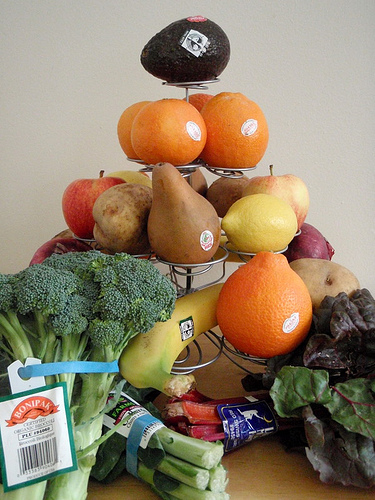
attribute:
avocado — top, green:
[140, 15, 232, 82]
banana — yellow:
[121, 284, 225, 398]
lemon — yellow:
[218, 194, 297, 252]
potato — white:
[95, 179, 150, 251]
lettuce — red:
[271, 288, 375, 492]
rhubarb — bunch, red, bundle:
[164, 385, 288, 450]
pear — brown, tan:
[145, 158, 222, 262]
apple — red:
[62, 169, 128, 239]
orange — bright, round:
[132, 97, 208, 165]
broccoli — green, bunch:
[2, 247, 179, 499]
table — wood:
[80, 304, 373, 498]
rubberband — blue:
[7, 361, 122, 376]